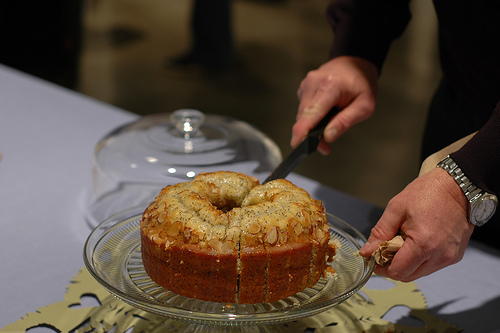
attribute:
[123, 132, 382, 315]
cake — tan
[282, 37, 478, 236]
shirt — black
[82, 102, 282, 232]
lid — clear